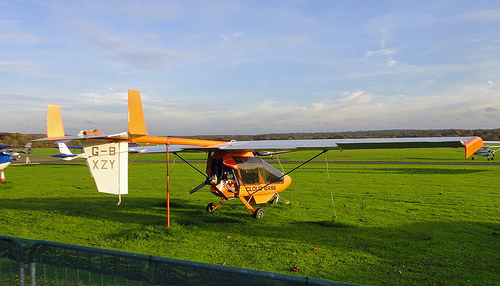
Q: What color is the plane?
A: Yellow.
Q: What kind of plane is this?
A: G-B XZY.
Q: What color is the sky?
A: Blue.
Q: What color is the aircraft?
A: Yellow.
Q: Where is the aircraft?
A: In a field.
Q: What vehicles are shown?
A: Planes.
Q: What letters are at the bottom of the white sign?
A: XYZ.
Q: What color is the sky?
A: Light blue.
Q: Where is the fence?
A: On the edge of the field.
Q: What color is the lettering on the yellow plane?
A: Black.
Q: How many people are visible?
A: None.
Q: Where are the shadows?
A: On the grass.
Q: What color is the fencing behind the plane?
A: Black.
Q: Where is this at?
A: A field.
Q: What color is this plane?
A: Yellow.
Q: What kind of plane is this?
A: G-B XZY.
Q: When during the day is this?
A: Afternoon.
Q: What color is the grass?
A: Green.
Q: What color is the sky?
A: Blue.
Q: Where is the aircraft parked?
A: In the grass on a field.